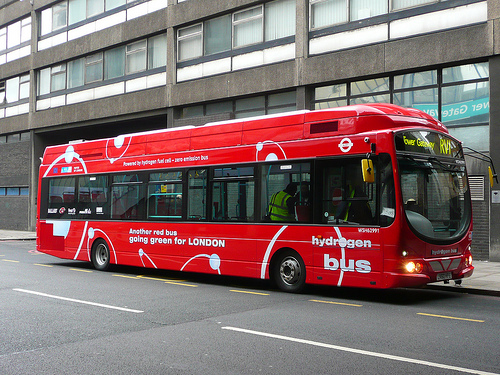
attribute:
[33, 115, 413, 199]
bus — red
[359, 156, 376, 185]
rearview mirror — large, rectangular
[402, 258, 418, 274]
bus headlight — on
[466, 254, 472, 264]
bus headlight — on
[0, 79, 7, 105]
window — open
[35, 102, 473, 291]
passenger bus — large, red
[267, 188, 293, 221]
vest — bright, yellow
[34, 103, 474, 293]
bus — big, parked, red, yellow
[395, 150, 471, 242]
windshield — large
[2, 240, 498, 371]
road — black, concrete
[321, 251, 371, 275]
word bus — white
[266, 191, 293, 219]
vest — neon yellow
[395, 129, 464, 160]
head sign — yellow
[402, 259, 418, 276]
headlight — on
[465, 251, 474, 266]
headlight — on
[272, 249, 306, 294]
wheel — black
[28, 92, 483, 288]
bus — red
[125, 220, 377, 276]
words — white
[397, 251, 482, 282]
lights — glowing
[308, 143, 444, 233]
window — glass